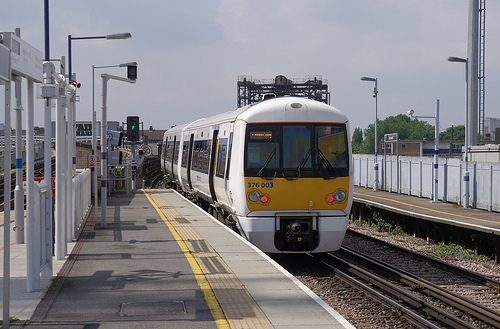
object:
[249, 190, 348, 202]
headlights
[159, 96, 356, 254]
train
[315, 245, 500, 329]
tracks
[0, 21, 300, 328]
station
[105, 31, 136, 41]
lighting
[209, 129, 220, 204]
door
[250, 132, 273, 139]
sign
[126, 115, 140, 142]
light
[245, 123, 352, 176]
windshield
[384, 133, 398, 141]
sign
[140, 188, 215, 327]
line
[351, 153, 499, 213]
wall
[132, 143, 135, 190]
pole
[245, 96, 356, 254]
front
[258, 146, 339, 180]
wipers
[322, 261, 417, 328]
gravel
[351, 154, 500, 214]
fence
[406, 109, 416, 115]
lamp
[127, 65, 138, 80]
camers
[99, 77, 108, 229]
pole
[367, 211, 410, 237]
weeds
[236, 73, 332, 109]
structure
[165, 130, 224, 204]
doors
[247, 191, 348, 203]
lights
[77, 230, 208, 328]
cement